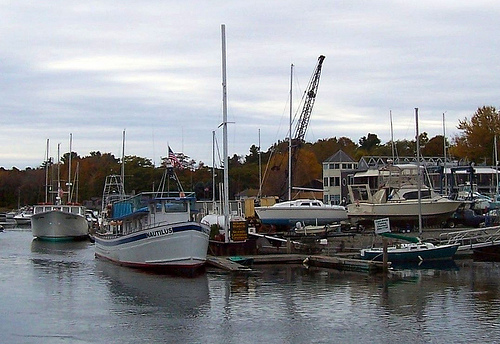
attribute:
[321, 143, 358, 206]
building — beige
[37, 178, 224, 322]
boats — docked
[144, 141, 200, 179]
flag — waving, american, flying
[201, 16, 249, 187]
mast — tall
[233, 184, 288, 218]
building — beige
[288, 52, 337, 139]
crane — long, tall, large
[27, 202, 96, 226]
windows — glass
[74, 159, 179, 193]
trees — growing, autumn, orange, brown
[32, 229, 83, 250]
boat — blue, named, striped, white, here, parked, reflected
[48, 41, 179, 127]
sky — cloudy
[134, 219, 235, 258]
boat — white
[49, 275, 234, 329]
water — rippled, calm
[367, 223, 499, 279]
boat — speedy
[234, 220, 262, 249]
barrel — wooden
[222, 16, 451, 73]
skies — overcast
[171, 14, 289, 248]
pole — tall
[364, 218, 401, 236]
sign — white